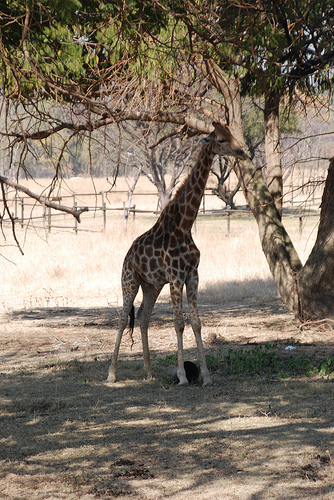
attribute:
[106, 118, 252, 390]
giraffe — dropping, standing, eating, brown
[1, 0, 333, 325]
tree — dying, green, standing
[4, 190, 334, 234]
fence — wooden, rickety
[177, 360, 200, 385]
dish — black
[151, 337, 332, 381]
grass — green, dry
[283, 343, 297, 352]
paper — white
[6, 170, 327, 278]
field — behind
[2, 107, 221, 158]
branch — bare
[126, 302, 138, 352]
tail — dark